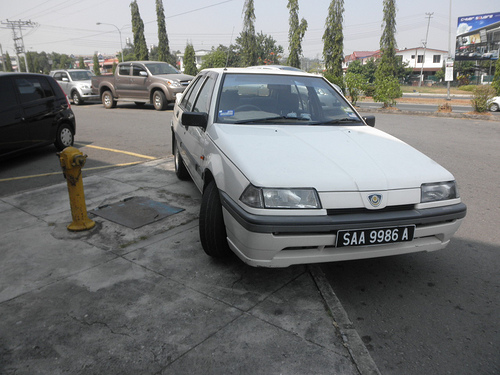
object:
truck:
[91, 60, 195, 110]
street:
[78, 110, 158, 160]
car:
[49, 68, 96, 104]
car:
[171, 65, 467, 268]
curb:
[87, 193, 185, 229]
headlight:
[239, 184, 322, 208]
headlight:
[421, 180, 457, 200]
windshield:
[215, 74, 369, 126]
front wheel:
[198, 186, 222, 259]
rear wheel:
[173, 149, 187, 180]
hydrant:
[57, 147, 95, 230]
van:
[2, 73, 76, 147]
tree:
[373, 4, 402, 101]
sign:
[455, 12, 495, 58]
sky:
[182, 11, 240, 38]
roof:
[354, 51, 376, 56]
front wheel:
[73, 92, 84, 105]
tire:
[153, 90, 169, 110]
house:
[399, 45, 447, 86]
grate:
[90, 196, 186, 229]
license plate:
[337, 224, 414, 246]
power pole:
[0, 18, 29, 72]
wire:
[38, 6, 72, 32]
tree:
[321, 1, 342, 89]